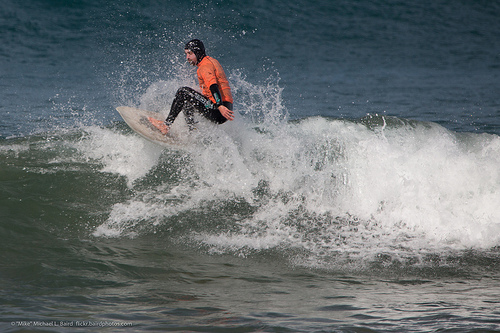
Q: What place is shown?
A: It is an ocean.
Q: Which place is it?
A: It is an ocean.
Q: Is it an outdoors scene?
A: Yes, it is outdoors.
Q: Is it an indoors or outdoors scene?
A: It is outdoors.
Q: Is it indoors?
A: No, it is outdoors.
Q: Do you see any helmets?
A: No, there are no helmets.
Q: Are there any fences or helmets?
A: No, there are no helmets or fences.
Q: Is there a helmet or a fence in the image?
A: No, there are no helmets or fences.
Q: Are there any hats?
A: Yes, there is a hat.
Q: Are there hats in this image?
A: Yes, there is a hat.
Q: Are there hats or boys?
A: Yes, there is a hat.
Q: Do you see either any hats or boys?
A: Yes, there is a hat.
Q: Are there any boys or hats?
A: Yes, there is a hat.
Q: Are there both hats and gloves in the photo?
A: No, there is a hat but no gloves.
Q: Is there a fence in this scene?
A: No, there are no fences.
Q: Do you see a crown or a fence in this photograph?
A: No, there are no fences or crowns.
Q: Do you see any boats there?
A: No, there are no boats.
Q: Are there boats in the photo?
A: No, there are no boats.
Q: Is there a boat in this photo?
A: No, there are no boats.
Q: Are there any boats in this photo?
A: No, there are no boats.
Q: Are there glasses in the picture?
A: No, there are no glasses.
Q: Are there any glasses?
A: No, there are no glasses.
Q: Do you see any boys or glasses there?
A: No, there are no glasses or boys.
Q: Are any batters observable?
A: No, there are no batters.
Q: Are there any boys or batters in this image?
A: No, there are no batters or boys.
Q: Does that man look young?
A: Yes, the man is young.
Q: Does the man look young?
A: Yes, the man is young.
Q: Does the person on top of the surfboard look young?
A: Yes, the man is young.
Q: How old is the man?
A: The man is young.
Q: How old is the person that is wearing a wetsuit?
A: The man is young.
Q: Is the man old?
A: No, the man is young.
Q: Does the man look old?
A: No, the man is young.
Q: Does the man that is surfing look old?
A: No, the man is young.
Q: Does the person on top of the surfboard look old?
A: No, the man is young.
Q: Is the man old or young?
A: The man is young.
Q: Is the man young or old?
A: The man is young.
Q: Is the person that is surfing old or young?
A: The man is young.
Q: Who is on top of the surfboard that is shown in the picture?
A: The man is on top of the surfboard.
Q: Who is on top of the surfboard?
A: The man is on top of the surfboard.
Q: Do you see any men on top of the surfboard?
A: Yes, there is a man on top of the surfboard.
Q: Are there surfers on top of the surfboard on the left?
A: No, there is a man on top of the surfboard.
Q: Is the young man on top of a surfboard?
A: Yes, the man is on top of a surfboard.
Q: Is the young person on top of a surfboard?
A: Yes, the man is on top of a surfboard.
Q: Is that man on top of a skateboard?
A: No, the man is on top of a surfboard.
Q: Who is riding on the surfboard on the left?
A: The man is riding on the surfboard.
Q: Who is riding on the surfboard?
A: The man is riding on the surfboard.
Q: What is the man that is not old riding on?
A: The man is riding on the surfboard.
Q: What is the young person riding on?
A: The man is riding on the surfboard.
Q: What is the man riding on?
A: The man is riding on the surfboard.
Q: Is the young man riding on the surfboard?
A: Yes, the man is riding on the surfboard.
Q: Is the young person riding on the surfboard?
A: Yes, the man is riding on the surfboard.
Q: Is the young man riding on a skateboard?
A: No, the man is riding on the surfboard.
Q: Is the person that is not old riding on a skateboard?
A: No, the man is riding on the surfboard.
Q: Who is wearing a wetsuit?
A: The man is wearing a wetsuit.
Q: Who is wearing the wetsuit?
A: The man is wearing a wetsuit.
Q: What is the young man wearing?
A: The man is wearing a wet suit.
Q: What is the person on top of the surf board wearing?
A: The man is wearing a wet suit.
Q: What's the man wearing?
A: The man is wearing a wet suit.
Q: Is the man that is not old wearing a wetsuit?
A: Yes, the man is wearing a wetsuit.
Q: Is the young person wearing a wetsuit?
A: Yes, the man is wearing a wetsuit.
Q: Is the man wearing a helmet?
A: No, the man is wearing a wetsuit.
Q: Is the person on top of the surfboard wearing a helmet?
A: No, the man is wearing a wetsuit.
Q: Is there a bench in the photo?
A: No, there are no benches.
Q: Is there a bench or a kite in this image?
A: No, there are no benches or kites.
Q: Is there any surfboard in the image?
A: Yes, there is a surfboard.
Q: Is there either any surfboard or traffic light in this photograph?
A: Yes, there is a surfboard.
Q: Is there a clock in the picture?
A: No, there are no clocks.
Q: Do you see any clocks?
A: No, there are no clocks.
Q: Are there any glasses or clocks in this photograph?
A: No, there are no clocks or glasses.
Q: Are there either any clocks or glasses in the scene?
A: No, there are no clocks or glasses.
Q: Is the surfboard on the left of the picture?
A: Yes, the surfboard is on the left of the image.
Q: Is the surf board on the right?
A: No, the surf board is on the left of the image.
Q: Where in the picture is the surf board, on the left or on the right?
A: The surf board is on the left of the image.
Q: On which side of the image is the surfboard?
A: The surfboard is on the left of the image.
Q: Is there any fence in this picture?
A: No, there are no fences.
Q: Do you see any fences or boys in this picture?
A: No, there are no fences or boys.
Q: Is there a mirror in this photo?
A: No, there are no mirrors.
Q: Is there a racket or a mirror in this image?
A: No, there are no mirrors or rackets.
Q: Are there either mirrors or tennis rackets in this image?
A: No, there are no mirrors or tennis rackets.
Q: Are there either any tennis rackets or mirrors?
A: No, there are no mirrors or tennis rackets.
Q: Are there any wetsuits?
A: Yes, there is a wetsuit.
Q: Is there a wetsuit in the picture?
A: Yes, there is a wetsuit.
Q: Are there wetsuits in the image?
A: Yes, there is a wetsuit.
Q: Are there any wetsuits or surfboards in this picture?
A: Yes, there is a wetsuit.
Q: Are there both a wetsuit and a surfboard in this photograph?
A: Yes, there are both a wetsuit and a surfboard.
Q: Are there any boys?
A: No, there are no boys.